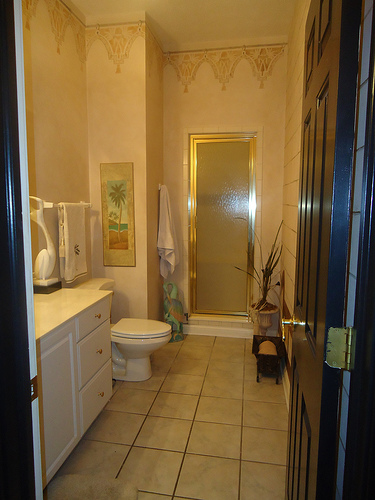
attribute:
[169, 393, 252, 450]
floor — brown, light, tiled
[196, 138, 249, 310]
shower door — gold edged, gold trimmed, frosted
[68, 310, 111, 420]
cabinets — white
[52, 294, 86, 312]
counter top — white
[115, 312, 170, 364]
toilet — white, ceramic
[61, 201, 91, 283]
towel — white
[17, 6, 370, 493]
bathroom — brown, dark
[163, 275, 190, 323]
sculpture — small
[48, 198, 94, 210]
towel holder — wooden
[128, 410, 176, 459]
tile — cream colored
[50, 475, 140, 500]
bathroom rug — white, fuzzy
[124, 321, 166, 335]
toilet seat — white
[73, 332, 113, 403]
drawers — white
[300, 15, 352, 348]
bathroom door — black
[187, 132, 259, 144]
trim — gold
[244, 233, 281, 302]
plant — large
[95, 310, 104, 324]
handles — gold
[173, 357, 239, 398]
tiles — white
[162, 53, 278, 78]
border — gold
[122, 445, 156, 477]
tile floor — off-white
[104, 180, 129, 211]
tree — palm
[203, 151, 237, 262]
mirror — big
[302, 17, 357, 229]
door — brown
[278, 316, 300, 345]
handle — silver